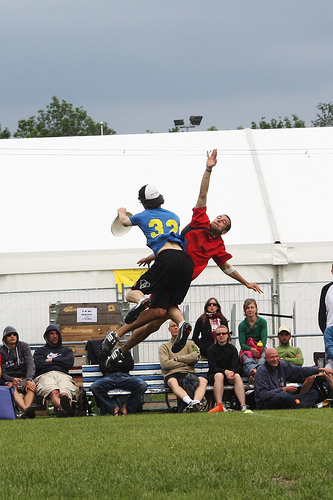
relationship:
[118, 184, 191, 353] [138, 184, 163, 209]
man wearing hat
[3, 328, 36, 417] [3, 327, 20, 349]
man wearing hood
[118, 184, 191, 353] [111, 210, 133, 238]
man playing frisbee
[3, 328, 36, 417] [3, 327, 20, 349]
man in hood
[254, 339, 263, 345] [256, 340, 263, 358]
top of water bottle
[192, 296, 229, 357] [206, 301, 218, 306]
woman has sunglasses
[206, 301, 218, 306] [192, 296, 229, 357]
sunglasses on woman